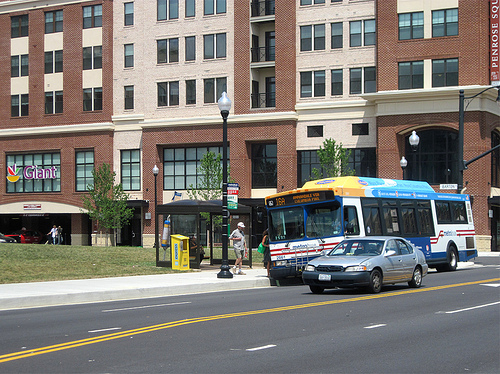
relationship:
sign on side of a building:
[487, 3, 499, 93] [55, 80, 483, 173]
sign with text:
[487, 3, 499, 93] [474, 43, 475, 45]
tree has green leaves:
[85, 171, 135, 249] [93, 167, 131, 232]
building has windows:
[5, 9, 479, 186] [13, 12, 447, 101]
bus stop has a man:
[153, 190, 266, 278] [226, 222, 250, 278]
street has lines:
[10, 288, 489, 364] [19, 291, 483, 372]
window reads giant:
[2, 149, 67, 194] [18, 160, 60, 184]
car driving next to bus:
[304, 232, 434, 299] [260, 163, 490, 269]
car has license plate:
[304, 232, 434, 299] [316, 271, 336, 285]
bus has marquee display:
[260, 163, 490, 269] [266, 186, 329, 210]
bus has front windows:
[260, 163, 490, 269] [269, 200, 341, 238]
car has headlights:
[304, 232, 434, 299] [306, 257, 370, 278]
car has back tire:
[304, 232, 434, 299] [407, 263, 425, 289]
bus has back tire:
[260, 163, 490, 269] [441, 240, 460, 277]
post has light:
[217, 109, 237, 287] [218, 91, 234, 113]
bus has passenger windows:
[260, 163, 490, 269] [355, 193, 469, 236]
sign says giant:
[7, 156, 62, 191] [18, 160, 60, 184]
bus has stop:
[260, 163, 490, 269] [153, 190, 266, 278]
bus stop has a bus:
[153, 190, 266, 278] [260, 163, 490, 269]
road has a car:
[10, 288, 489, 364] [304, 232, 434, 299]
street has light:
[10, 288, 489, 364] [218, 91, 234, 113]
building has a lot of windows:
[5, 9, 479, 186] [13, 12, 447, 101]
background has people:
[1, 190, 153, 261] [19, 217, 65, 249]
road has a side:
[22, 306, 339, 373] [14, 289, 249, 314]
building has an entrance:
[17, 18, 116, 255] [3, 207, 72, 255]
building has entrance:
[17, 18, 116, 255] [0, 207, 72, 246]